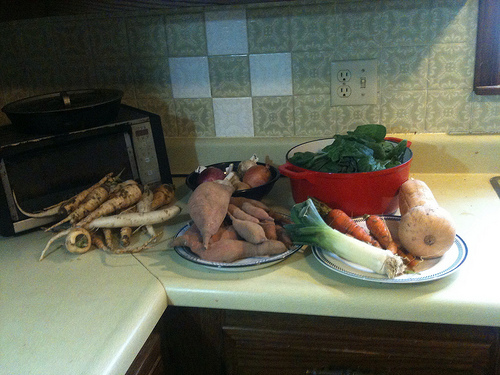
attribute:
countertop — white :
[25, 152, 495, 368]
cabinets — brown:
[199, 314, 439, 372]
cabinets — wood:
[173, 296, 497, 371]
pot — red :
[288, 162, 403, 202]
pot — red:
[277, 135, 412, 215]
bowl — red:
[284, 167, 394, 212]